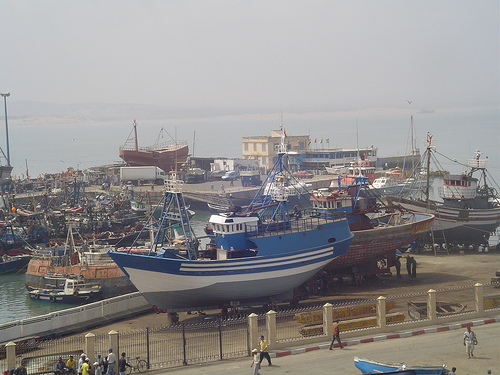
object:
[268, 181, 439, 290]
boats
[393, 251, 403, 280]
people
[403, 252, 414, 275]
people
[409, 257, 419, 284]
people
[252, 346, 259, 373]
person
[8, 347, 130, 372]
people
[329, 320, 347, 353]
person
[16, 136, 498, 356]
boat dock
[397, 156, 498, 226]
boat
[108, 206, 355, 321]
man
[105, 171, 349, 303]
boats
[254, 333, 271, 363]
person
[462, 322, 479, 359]
person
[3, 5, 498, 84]
sky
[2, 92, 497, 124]
land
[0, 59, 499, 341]
construction area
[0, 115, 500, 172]
water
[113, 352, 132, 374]
person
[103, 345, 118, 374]
person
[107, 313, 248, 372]
railing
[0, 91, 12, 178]
mast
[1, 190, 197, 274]
barge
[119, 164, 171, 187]
truck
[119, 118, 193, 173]
ship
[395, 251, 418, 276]
workers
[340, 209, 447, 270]
boat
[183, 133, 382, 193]
building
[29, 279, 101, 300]
boat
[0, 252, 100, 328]
water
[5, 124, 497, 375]
harbor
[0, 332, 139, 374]
crowd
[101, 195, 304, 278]
boat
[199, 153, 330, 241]
structures